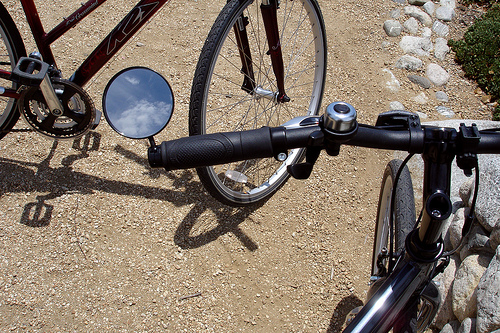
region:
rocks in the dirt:
[371, 2, 468, 121]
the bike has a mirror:
[100, 63, 176, 140]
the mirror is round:
[98, 65, 177, 140]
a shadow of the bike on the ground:
[0, 124, 263, 259]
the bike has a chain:
[0, 71, 95, 139]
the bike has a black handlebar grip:
[157, 119, 276, 173]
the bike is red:
[0, 0, 330, 209]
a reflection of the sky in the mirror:
[100, 65, 177, 144]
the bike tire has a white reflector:
[222, 169, 250, 186]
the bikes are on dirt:
[1, 1, 494, 331]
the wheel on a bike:
[159, 0, 396, 195]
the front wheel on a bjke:
[157, 0, 381, 195]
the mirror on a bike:
[69, 51, 214, 171]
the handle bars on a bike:
[139, 85, 494, 198]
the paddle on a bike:
[16, 32, 81, 117]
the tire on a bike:
[166, 28, 268, 199]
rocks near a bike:
[385, 3, 487, 110]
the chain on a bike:
[13, 115, 43, 145]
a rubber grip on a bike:
[146, 102, 305, 199]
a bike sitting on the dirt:
[116, 16, 405, 218]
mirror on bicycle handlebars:
[96, 54, 199, 155]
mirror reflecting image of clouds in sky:
[99, 66, 201, 161]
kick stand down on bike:
[12, 3, 124, 198]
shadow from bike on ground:
[6, 127, 268, 262]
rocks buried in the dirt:
[371, 23, 490, 98]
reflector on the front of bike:
[375, 93, 422, 135]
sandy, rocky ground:
[9, 6, 474, 328]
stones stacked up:
[431, 112, 499, 327]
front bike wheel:
[179, 9, 350, 209]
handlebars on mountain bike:
[91, 49, 498, 164]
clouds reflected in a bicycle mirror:
[94, 62, 191, 146]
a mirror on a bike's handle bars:
[91, 60, 185, 152]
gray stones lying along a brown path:
[381, 4, 486, 137]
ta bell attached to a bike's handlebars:
[302, 96, 367, 166]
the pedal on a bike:
[9, 52, 49, 101]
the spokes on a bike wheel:
[187, 3, 334, 208]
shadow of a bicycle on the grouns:
[0, 127, 265, 273]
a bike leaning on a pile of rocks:
[99, 60, 498, 330]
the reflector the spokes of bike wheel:
[225, 165, 253, 187]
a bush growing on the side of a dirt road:
[452, 5, 498, 90]